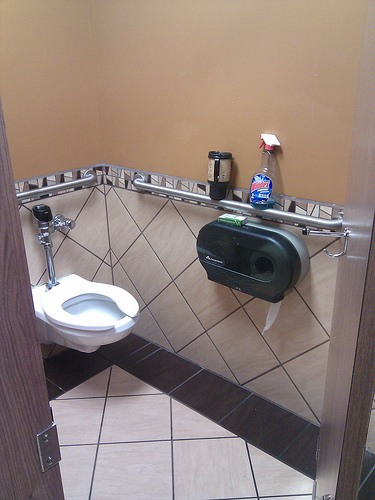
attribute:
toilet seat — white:
[43, 280, 141, 333]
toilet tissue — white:
[249, 240, 290, 337]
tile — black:
[43, 332, 374, 496]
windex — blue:
[247, 130, 282, 208]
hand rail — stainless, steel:
[134, 173, 346, 230]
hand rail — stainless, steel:
[17, 169, 98, 198]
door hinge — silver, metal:
[35, 422, 63, 471]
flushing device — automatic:
[32, 202, 53, 221]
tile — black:
[163, 367, 245, 424]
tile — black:
[126, 345, 203, 390]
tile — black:
[219, 392, 321, 479]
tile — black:
[101, 329, 163, 369]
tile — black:
[40, 347, 106, 392]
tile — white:
[168, 392, 245, 439]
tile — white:
[245, 439, 314, 496]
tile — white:
[54, 441, 98, 498]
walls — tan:
[0, 0, 375, 437]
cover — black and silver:
[196, 214, 311, 304]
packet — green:
[211, 208, 253, 228]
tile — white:
[172, 437, 259, 499]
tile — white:
[87, 437, 173, 497]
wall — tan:
[0, 0, 375, 430]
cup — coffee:
[206, 150, 234, 202]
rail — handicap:
[130, 176, 345, 230]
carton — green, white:
[216, 209, 246, 226]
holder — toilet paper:
[186, 212, 314, 301]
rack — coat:
[300, 223, 351, 257]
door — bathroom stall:
[306, 2, 361, 495]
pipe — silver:
[28, 206, 74, 286]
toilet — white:
[28, 272, 139, 354]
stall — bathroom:
[4, 6, 348, 494]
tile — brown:
[198, 298, 288, 390]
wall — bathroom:
[86, 3, 346, 440]